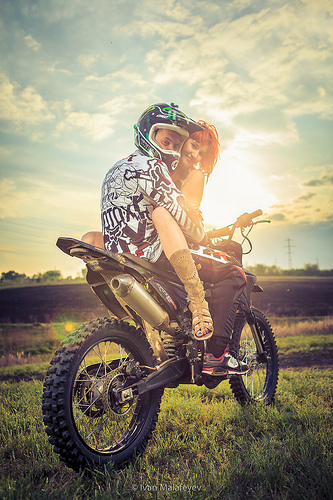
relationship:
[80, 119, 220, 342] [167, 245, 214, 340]
girl wearing boot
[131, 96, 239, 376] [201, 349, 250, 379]
man wearing black shoe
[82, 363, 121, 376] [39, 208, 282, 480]
chain on motorbike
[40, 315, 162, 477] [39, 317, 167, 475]
wheel spokes on tire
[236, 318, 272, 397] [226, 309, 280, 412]
spokes on wheel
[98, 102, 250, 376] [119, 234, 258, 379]
man wearing pants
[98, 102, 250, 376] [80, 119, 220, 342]
man holding girl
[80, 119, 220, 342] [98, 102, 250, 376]
girl holding man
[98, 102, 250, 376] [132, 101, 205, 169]
man wearing helmet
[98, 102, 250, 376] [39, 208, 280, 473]
man on a motorbike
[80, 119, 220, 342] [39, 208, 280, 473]
girl on a motorbike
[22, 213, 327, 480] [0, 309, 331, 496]
motorbike sitting on grass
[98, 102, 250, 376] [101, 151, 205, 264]
man wearing shirt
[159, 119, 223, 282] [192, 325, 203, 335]
girl has toenail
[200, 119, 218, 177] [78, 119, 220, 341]
hair on girl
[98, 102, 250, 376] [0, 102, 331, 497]
man in foreground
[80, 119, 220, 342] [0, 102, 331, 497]
girl in foreground